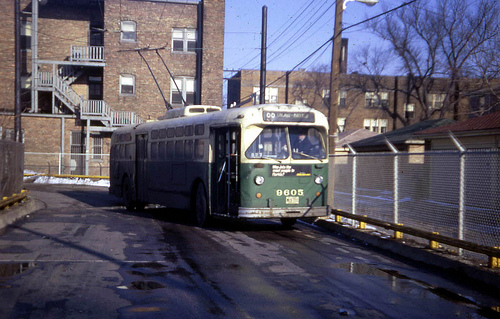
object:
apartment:
[0, 1, 224, 182]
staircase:
[33, 63, 133, 133]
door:
[211, 125, 241, 216]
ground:
[0, 183, 499, 319]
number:
[276, 188, 303, 196]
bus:
[109, 104, 330, 226]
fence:
[326, 147, 500, 258]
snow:
[43, 162, 85, 192]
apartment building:
[227, 68, 500, 133]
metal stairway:
[21, 44, 144, 132]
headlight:
[255, 176, 265, 185]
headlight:
[314, 176, 324, 184]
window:
[171, 27, 198, 52]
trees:
[288, 0, 500, 133]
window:
[120, 20, 138, 41]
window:
[119, 73, 136, 96]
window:
[169, 75, 196, 106]